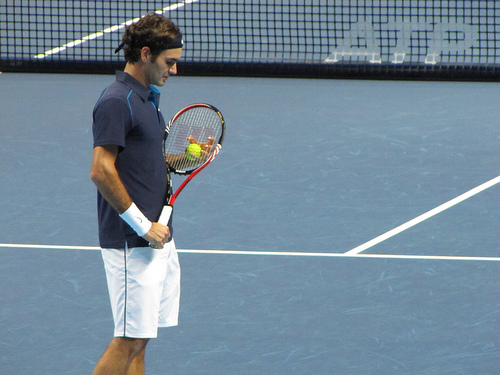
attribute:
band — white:
[115, 199, 154, 241]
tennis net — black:
[1, 0, 498, 85]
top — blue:
[56, 89, 238, 213]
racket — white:
[163, 103, 230, 240]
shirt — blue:
[89, 76, 179, 254]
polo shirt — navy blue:
[90, 67, 175, 248]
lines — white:
[268, 186, 441, 286]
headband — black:
[112, 35, 191, 51]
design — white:
[179, 33, 185, 46]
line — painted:
[0, 241, 500, 262]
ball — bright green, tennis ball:
[185, 142, 202, 161]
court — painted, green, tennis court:
[15, 60, 497, 354]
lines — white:
[194, 160, 492, 294]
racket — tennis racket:
[146, 104, 241, 233]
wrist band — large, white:
[121, 192, 163, 248]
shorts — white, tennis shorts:
[58, 207, 230, 344]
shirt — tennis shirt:
[88, 71, 187, 249]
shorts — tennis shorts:
[102, 227, 184, 341]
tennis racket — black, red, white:
[153, 102, 225, 235]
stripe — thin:
[120, 242, 128, 337]